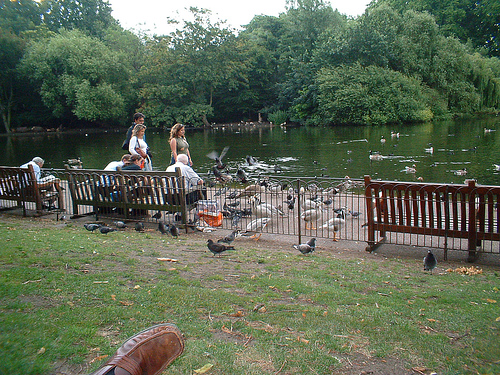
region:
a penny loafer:
[91, 306, 192, 371]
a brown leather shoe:
[93, 305, 205, 374]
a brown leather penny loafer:
[92, 306, 202, 373]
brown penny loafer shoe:
[98, 312, 198, 374]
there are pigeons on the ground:
[51, 218, 456, 298]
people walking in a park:
[116, 92, 206, 184]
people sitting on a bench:
[91, 141, 219, 221]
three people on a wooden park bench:
[61, 146, 219, 230]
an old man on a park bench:
[12, 144, 66, 202]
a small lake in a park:
[56, 118, 495, 188]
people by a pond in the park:
[65, 108, 207, 227]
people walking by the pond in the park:
[121, 109, 188, 166]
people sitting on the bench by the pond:
[95, 151, 205, 206]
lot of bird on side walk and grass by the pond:
[204, 181, 356, 255]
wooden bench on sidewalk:
[356, 175, 498, 255]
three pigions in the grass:
[201, 235, 447, 272]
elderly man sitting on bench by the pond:
[0, 156, 65, 213]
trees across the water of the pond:
[1, 61, 497, 124]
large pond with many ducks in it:
[1, 114, 498, 181]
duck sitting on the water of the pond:
[367, 149, 384, 161]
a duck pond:
[17, 122, 490, 177]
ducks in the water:
[346, 125, 496, 180]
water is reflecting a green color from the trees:
[15, 111, 490, 176]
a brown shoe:
[80, 330, 190, 372]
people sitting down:
[75, 155, 200, 210]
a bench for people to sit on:
[350, 165, 495, 245]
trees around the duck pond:
[5, 0, 496, 120]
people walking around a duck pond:
[120, 110, 190, 210]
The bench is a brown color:
[365, 174, 499, 256]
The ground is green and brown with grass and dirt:
[7, 239, 499, 371]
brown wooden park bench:
[361, 178, 496, 250]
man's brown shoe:
[89, 323, 181, 373]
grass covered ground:
[2, 216, 497, 369]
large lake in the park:
[0, 127, 497, 184]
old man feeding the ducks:
[164, 155, 203, 195]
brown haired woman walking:
[171, 123, 191, 165]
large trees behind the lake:
[3, 3, 495, 123]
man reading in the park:
[20, 158, 60, 208]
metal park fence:
[5, 168, 492, 248]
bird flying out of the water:
[212, 149, 228, 169]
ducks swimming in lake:
[359, 123, 496, 180]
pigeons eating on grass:
[75, 214, 443, 271]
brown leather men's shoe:
[94, 325, 186, 370]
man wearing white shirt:
[165, 156, 203, 201]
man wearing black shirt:
[119, 158, 146, 193]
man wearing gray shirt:
[99, 157, 125, 192]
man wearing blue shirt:
[19, 157, 44, 189]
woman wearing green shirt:
[171, 124, 189, 161]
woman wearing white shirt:
[131, 124, 144, 151]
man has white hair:
[175, 151, 190, 165]